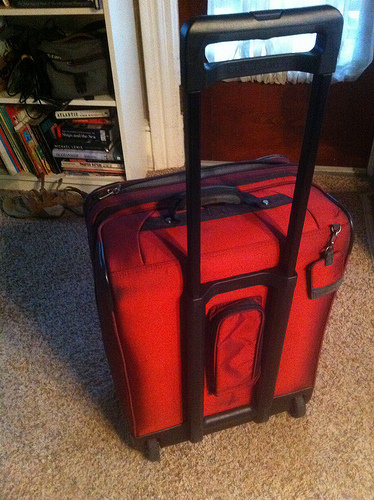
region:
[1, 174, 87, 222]
well worn pair of leather sandles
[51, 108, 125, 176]
vertical stack of books on bottom shelf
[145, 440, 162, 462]
small black wheel on suitcase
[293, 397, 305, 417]
small black wheel on suitcase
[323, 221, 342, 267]
zipper pull with tag attached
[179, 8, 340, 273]
extended handle for pulling suitcase while on its wheels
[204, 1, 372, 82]
sheer curtain over window in the door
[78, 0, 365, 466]
red and black travel case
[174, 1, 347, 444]
retractable black handle on case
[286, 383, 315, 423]
black wheel on bottom of case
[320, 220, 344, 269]
black metal zipper in corner of case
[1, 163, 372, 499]
plush brown carpeting on floor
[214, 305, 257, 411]
curvy stain on back of travel case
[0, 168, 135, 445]
shadow of case on carpet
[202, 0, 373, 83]
gauzy light blue curtain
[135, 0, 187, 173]
painted white frame of closet door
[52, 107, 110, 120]
book on a shelf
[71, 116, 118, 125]
book on a shelf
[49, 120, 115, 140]
book on a shelf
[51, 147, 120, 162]
book on a shelf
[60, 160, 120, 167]
book on a shelf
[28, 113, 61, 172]
book on a shelf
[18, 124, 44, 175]
book on a shelf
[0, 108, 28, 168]
book on a shelf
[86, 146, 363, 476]
This is a bag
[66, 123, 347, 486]
This is a red bag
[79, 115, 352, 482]
This is a suite case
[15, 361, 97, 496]
section of a floor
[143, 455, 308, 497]
section of a floor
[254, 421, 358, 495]
section of a floor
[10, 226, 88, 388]
section of a floor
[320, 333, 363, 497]
section of a floor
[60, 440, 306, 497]
section of a floor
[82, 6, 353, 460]
piece of luggage with wheels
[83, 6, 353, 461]
red colored luggage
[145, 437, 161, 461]
left wheel of luggage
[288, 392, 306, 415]
right wheel of luggage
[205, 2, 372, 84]
window covered with curtain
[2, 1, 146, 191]
white bookshelf with filled shelves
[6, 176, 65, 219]
sandal on the floor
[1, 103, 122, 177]
group of books on a shelf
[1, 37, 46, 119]
black wire on a shelf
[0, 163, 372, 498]
tan carpet covering the floor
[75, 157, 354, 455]
The red suitcase.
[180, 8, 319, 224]
The black handle.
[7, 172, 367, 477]
The tan carpet.